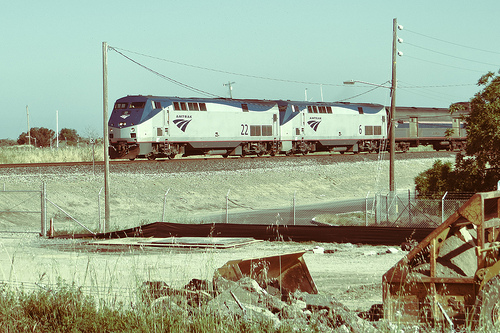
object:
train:
[106, 92, 499, 163]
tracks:
[0, 145, 497, 168]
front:
[106, 93, 149, 160]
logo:
[170, 113, 194, 131]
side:
[140, 99, 387, 143]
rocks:
[1, 151, 469, 185]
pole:
[101, 42, 111, 235]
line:
[105, 47, 372, 88]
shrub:
[410, 68, 499, 214]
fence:
[1, 183, 499, 242]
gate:
[1, 184, 44, 237]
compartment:
[406, 115, 419, 135]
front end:
[379, 191, 484, 320]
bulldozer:
[380, 191, 500, 333]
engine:
[105, 94, 391, 161]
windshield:
[114, 100, 147, 112]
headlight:
[128, 126, 138, 137]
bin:
[210, 250, 318, 318]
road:
[3, 230, 441, 322]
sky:
[0, 1, 498, 142]